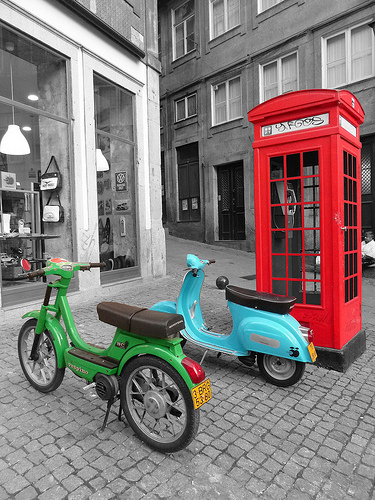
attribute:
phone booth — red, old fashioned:
[247, 89, 366, 373]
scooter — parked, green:
[15, 256, 212, 453]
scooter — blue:
[148, 254, 318, 386]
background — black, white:
[0, 1, 375, 499]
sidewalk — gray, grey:
[1, 222, 374, 497]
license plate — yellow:
[191, 378, 213, 412]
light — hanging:
[1, 40, 31, 156]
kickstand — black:
[99, 396, 124, 434]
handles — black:
[14, 261, 106, 281]